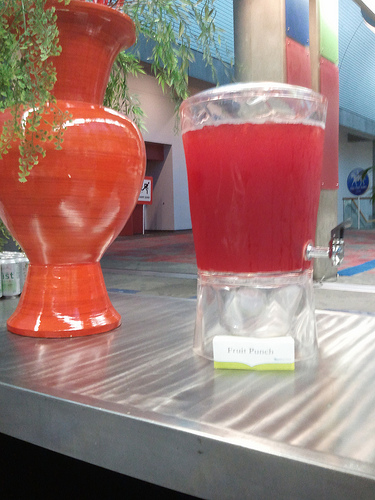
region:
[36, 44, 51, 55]
Small green leaf of a plant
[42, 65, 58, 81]
Small green leaf of a plant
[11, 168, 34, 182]
Small green leaf of a plant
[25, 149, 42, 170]
Small green leaf of a plant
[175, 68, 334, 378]
Red drink in a clear container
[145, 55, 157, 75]
Small green leaf of a plant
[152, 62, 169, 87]
Small green leaf of a plant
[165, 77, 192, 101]
Small green leaf of a plant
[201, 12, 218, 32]
Small green leaf of a plant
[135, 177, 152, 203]
red and white sign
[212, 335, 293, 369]
the juice type card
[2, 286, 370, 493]
a metal counter top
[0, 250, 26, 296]
canned beverages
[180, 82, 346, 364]
iced juice in a plastic jug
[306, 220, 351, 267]
metal pouring spout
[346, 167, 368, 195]
blue circular sign on the building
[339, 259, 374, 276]
painted blue stripe on the ground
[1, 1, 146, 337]
orange vase with a house plant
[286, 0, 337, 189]
multi colored wall art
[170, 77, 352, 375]
Large dispenser of red colored juice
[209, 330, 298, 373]
Yellow sign that says fruit punch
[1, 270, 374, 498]
Metal shiny table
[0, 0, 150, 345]
Large orange shiny vase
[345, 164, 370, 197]
Circular blue painting on the wall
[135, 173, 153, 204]
Sign with a stick figure running on it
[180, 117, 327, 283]
Sweat dripping from the juice dispenser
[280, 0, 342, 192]
Colored tiles hanging on the wall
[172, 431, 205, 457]
Stain on the metal table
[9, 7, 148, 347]
large ceramic planter with green plant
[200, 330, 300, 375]
sign indicating fruit punch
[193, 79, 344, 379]
container filled with fruit punch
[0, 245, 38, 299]
white soda cans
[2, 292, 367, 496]
bright silver table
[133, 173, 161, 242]
red, white and black sign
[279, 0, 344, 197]
four retangles of color on column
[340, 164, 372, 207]
circular blue sign on wall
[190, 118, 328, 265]
red fruit punch in container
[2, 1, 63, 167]
green plant in orange vase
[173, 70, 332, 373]
A jug of fruit punch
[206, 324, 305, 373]
The sign says fruit punch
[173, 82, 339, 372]
The jug is made of glass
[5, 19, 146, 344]
A large glass vase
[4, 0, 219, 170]
A green plant in the vase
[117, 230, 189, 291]
Carpet on the ground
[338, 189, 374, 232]
A staircase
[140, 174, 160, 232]
A sign with a person on it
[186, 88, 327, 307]
big jar whit a red liquid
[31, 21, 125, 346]
orange vase on the table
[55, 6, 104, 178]
old orange pot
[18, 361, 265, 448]
metal counter with drinks on it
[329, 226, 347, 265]
metal beverage dispenser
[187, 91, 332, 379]
a jar with red drink in it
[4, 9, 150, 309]
a pot with a house plant in it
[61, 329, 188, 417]
a gray table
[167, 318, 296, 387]
a yellow tag that has fruit punch on it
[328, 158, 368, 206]
a blue and gray sing on the wall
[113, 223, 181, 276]
a red floor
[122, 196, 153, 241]
a red door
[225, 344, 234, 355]
black letter on sign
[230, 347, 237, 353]
black letter on sign